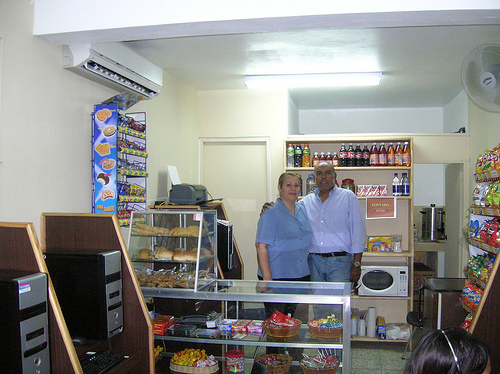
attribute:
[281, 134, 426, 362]
shelf — large, brown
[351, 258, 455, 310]
microwave — small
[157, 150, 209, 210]
printer — gray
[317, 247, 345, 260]
belt — black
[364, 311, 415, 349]
bowls — candy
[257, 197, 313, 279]
shirt — blue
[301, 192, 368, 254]
shirt — blue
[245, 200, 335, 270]
shirt — blue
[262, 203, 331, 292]
shirt — blue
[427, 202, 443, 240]
pot — coffee pot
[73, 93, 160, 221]
rack — cookie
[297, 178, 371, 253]
shirt — blue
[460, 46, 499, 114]
fan — white, large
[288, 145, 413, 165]
driinks — soda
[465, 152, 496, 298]
driinks — soda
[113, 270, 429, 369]
cabinet — glass